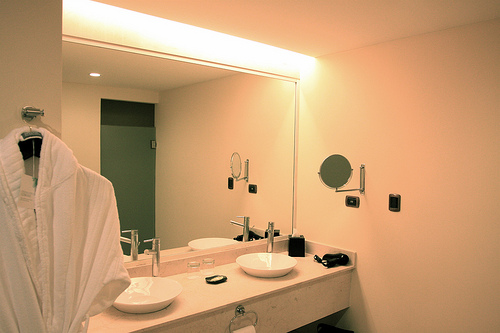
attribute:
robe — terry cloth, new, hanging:
[1, 127, 130, 332]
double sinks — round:
[237, 250, 297, 277]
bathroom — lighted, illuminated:
[1, 1, 498, 332]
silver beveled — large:
[63, 31, 298, 252]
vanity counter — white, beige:
[178, 273, 207, 312]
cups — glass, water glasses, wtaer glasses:
[187, 258, 204, 286]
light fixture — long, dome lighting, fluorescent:
[64, 0, 320, 79]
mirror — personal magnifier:
[319, 153, 366, 194]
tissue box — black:
[287, 233, 306, 257]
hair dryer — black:
[316, 252, 350, 267]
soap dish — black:
[205, 274, 227, 286]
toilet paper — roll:
[233, 316, 261, 333]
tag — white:
[18, 175, 35, 210]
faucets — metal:
[265, 221, 275, 254]